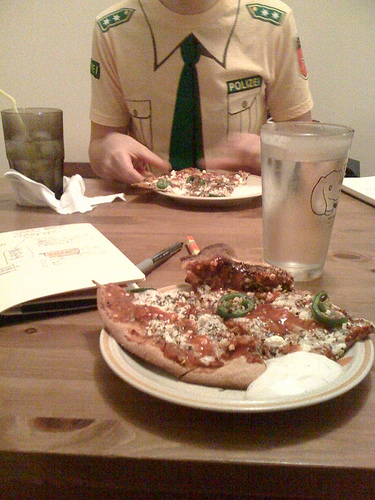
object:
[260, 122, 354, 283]
glass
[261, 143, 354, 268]
water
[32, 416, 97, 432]
knot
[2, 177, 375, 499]
table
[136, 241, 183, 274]
pen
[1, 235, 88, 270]
writing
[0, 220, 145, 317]
notebook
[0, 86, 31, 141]
straw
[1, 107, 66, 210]
glass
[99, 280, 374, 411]
plate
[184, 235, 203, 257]
pen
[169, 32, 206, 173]
tie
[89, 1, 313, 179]
shirt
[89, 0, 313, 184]
man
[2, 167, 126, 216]
napkin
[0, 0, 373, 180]
wall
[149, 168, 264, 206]
plate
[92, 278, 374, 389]
pizza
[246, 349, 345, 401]
sauce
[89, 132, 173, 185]
hand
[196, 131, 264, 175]
hand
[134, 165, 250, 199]
pizza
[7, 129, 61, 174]
ice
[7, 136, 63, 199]
water